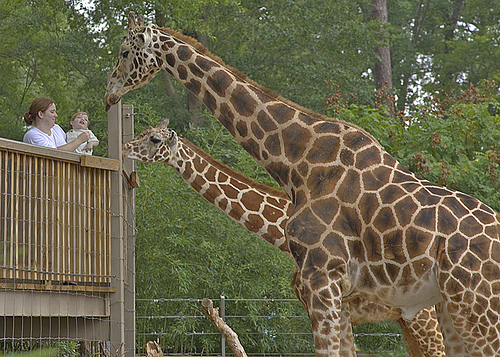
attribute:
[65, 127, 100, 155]
shirt — white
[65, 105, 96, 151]
child — afraid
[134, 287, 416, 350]
fence — metal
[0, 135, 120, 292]
wooden railing — brown colored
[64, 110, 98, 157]
child — small, smiling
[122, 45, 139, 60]
eye — black 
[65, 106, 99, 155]
hair — red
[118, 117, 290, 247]
giraffe — brown, tan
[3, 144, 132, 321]
fence — wooden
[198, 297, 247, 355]
tree branch — cut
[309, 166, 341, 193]
spots — black